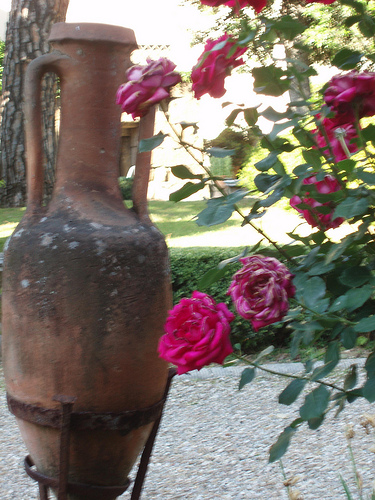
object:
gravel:
[0, 338, 374, 497]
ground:
[6, 186, 362, 492]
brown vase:
[0, 20, 171, 497]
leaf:
[299, 250, 373, 326]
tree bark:
[0, 0, 69, 203]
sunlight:
[144, 11, 318, 248]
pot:
[0, 17, 170, 499]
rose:
[230, 249, 295, 332]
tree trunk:
[0, 3, 61, 214]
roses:
[189, 30, 246, 98]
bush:
[167, 237, 371, 361]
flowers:
[155, 282, 233, 376]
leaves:
[197, 185, 249, 227]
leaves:
[328, 230, 351, 264]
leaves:
[267, 127, 290, 150]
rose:
[287, 167, 346, 228]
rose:
[114, 50, 177, 119]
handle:
[11, 46, 59, 232]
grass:
[149, 190, 218, 238]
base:
[9, 400, 165, 500]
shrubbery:
[299, 272, 374, 402]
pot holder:
[5, 365, 201, 498]